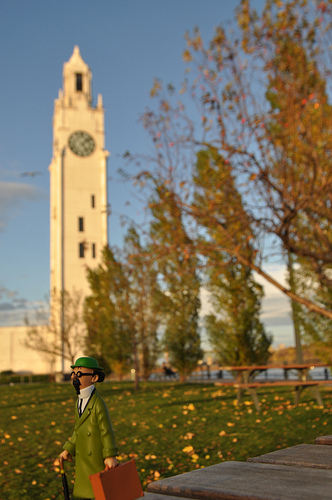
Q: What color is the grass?
A: Green.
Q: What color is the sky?
A: Blue.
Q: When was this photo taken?
A: Outside, during the daytime.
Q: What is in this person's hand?
A: A briefcase.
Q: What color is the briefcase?
A: Brown.